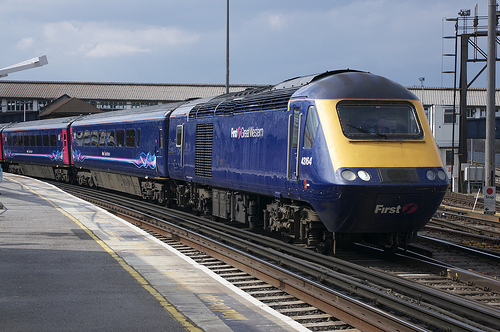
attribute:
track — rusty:
[384, 230, 499, 294]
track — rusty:
[417, 199, 499, 246]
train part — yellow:
[308, 97, 443, 168]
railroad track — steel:
[308, 259, 499, 330]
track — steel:
[265, 227, 486, 314]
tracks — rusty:
[285, 254, 415, 311]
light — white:
[435, 167, 448, 184]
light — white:
[426, 168, 436, 182]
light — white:
[357, 168, 372, 183]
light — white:
[338, 165, 356, 185]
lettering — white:
[222, 120, 268, 140]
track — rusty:
[60, 180, 497, 330]